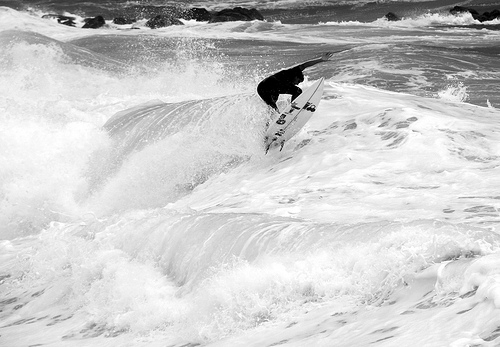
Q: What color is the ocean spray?
A: White.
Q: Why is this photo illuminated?
A: Sunlight.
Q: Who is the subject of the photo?
A: The surfer.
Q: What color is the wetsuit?
A: Black.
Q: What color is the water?
A: Gray.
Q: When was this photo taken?
A: During the day.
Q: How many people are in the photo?
A: One.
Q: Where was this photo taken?
A: At the beach.